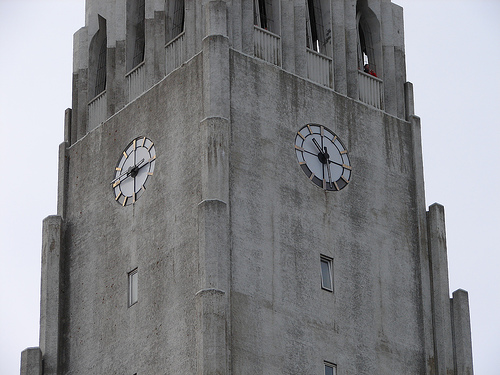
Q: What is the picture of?
A: A tower.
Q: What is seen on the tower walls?
A: Clocks.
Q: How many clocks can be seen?
A: Two.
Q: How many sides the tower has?
A: Four.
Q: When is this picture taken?
A: Daytime.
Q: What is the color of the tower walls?
A: Grey.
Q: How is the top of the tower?
A: The tower top has arched open windows for viewing.